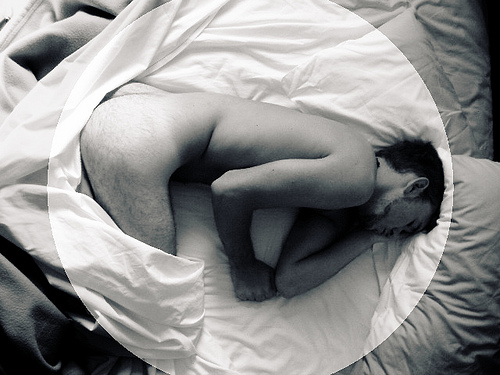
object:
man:
[81, 81, 446, 302]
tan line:
[75, 82, 176, 253]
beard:
[367, 200, 396, 236]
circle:
[47, 1, 454, 374]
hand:
[229, 259, 278, 302]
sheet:
[1, 2, 204, 372]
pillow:
[360, 155, 499, 374]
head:
[359, 139, 445, 239]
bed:
[1, 0, 499, 373]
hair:
[377, 140, 443, 204]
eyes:
[406, 219, 416, 228]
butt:
[78, 81, 164, 171]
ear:
[404, 176, 432, 196]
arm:
[210, 154, 375, 262]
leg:
[84, 164, 177, 255]